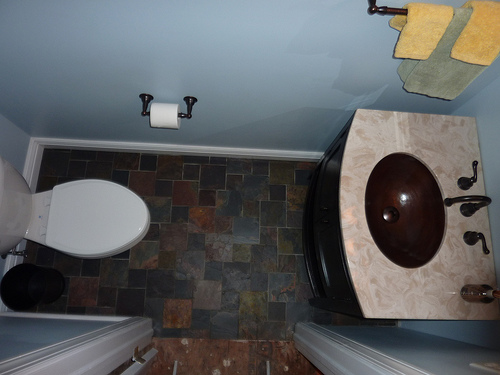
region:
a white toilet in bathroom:
[0, 145, 172, 269]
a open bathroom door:
[78, 314, 366, 374]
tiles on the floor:
[156, 183, 316, 326]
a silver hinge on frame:
[128, 343, 149, 369]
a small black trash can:
[0, 256, 77, 314]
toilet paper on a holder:
[145, 102, 184, 126]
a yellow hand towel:
[376, 0, 436, 58]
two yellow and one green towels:
[379, 0, 499, 112]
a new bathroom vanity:
[292, 98, 497, 343]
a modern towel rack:
[358, 0, 398, 22]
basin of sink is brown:
[373, 165, 445, 260]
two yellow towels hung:
[402, 9, 499, 61]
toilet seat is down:
[47, 185, 166, 263]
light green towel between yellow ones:
[407, 15, 472, 105]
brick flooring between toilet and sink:
[142, 163, 292, 333]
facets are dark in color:
[452, 152, 489, 275]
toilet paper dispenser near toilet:
[123, 93, 204, 149]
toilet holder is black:
[136, 92, 196, 128]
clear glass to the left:
[456, 277, 488, 318]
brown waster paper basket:
[0, 273, 72, 305]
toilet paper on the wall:
[132, 84, 205, 137]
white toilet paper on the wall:
[134, 88, 203, 135]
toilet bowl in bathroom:
[2, 149, 154, 271]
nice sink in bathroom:
[307, 102, 491, 317]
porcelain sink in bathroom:
[334, 98, 492, 326]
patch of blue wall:
[202, 33, 333, 138]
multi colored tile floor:
[165, 173, 296, 316]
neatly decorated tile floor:
[149, 163, 305, 316]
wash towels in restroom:
[392, 34, 497, 109]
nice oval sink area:
[363, 147, 452, 273]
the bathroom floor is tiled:
[148, 172, 298, 314]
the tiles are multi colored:
[156, 163, 291, 307]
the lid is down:
[12, 169, 179, 270]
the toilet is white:
[2, 160, 166, 275]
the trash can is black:
[3, 264, 88, 311]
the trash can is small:
[2, 260, 99, 322]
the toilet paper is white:
[130, 85, 195, 134]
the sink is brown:
[347, 140, 452, 270]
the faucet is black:
[440, 145, 494, 267]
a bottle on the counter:
[444, 268, 499, 315]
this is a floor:
[173, 173, 283, 284]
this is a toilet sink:
[36, 187, 153, 254]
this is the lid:
[65, 208, 114, 230]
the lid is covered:
[56, 183, 152, 235]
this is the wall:
[218, 20, 333, 127]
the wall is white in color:
[224, 33, 294, 135]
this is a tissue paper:
[143, 96, 175, 131]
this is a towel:
[406, 13, 451, 58]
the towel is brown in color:
[405, 22, 428, 62]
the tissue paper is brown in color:
[148, 104, 176, 128]